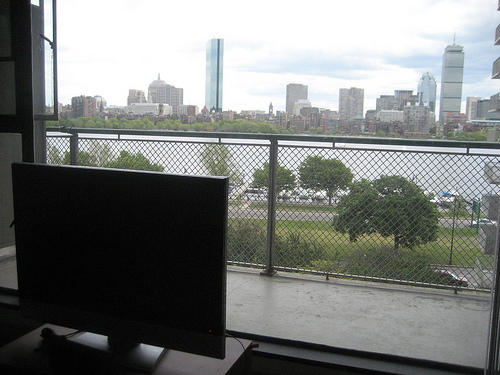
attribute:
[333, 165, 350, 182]
leaves — green 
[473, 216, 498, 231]
car — white 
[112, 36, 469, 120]
houses — tall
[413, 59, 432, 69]
sky — blue 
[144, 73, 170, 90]
house — dome shaped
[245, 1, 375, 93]
clouds — thick 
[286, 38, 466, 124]
buildings — tall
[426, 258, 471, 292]
car — black 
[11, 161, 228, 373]
tv — off, black 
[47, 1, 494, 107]
sky — bright 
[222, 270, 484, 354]
floor — grey 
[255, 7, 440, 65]
clouds — white 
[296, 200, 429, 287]
grass — green 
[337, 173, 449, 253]
tree — thick, green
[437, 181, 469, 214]
boat — small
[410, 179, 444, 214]
boat — small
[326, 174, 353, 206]
boat — small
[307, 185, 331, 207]
boat — small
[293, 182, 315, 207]
boat — small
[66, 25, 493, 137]
buildings — tall 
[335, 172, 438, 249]
tree — green 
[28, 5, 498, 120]
sky — cloudy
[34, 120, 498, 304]
fence — chain link, wire , meshed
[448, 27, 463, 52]
pole — tall